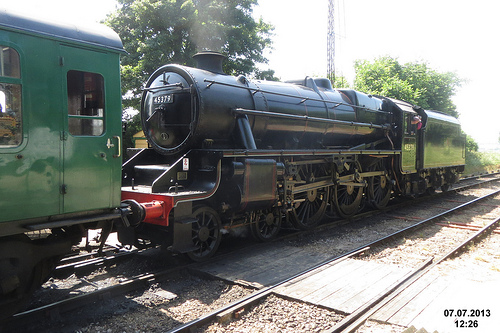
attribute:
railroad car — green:
[0, 8, 125, 297]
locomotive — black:
[120, 51, 468, 263]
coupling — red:
[119, 189, 176, 229]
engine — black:
[137, 54, 391, 158]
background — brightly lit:
[1, 0, 496, 166]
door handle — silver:
[110, 133, 123, 160]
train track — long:
[2, 169, 500, 332]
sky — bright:
[2, 0, 500, 114]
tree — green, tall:
[100, 0, 278, 147]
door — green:
[57, 39, 122, 216]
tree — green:
[331, 54, 470, 122]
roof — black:
[1, 0, 128, 53]